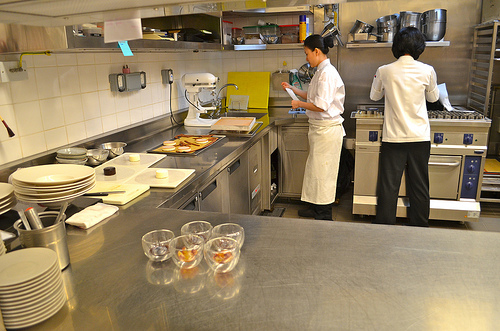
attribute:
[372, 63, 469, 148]
jacket — white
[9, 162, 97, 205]
plates — stacked, white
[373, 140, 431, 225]
pants — black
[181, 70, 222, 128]
mixer — white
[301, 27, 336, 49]
hair — black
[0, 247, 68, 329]
plates — clean 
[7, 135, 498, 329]
counter — stainless steel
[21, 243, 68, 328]
white plates — round 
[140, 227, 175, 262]
container — small, glass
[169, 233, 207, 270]
container — small, glass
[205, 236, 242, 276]
container — small, glass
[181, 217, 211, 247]
container — small, glass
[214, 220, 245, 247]
container — small, glass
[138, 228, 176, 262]
bowl — small, glass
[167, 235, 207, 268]
bowl — small, glass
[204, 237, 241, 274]
bowl — small, glass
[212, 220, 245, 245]
bowl — small, glass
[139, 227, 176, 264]
bowl — shiny, glass 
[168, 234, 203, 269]
bowl — shiny, glass 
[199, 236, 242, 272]
bowl — shiny, glass 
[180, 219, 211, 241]
bowl — small, glass, shiny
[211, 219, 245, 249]
bowl — shiny, glass 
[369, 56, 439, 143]
shirt — white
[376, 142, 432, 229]
pants — black